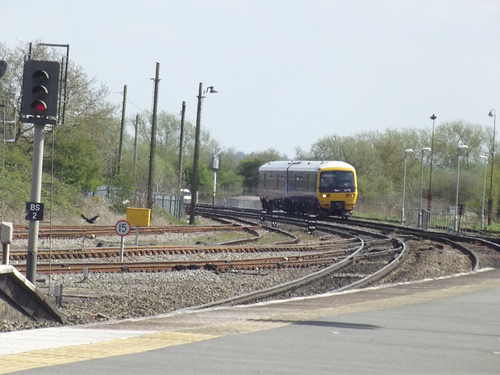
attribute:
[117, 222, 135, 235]
sign — round, small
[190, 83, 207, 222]
pole — wooden, brown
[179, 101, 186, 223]
pole — wooden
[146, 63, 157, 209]
pole — wooden, brown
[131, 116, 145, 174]
pole — wooden, brown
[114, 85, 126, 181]
pole — wooden, brown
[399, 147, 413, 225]
pole — white, metal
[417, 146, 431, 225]
pole — white, metal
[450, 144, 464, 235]
pole — white, metal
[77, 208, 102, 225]
bird — flying, black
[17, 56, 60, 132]
traffic signal — black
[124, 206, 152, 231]
box — yellow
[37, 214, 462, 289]
tracks — metal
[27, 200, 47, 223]
sign — small